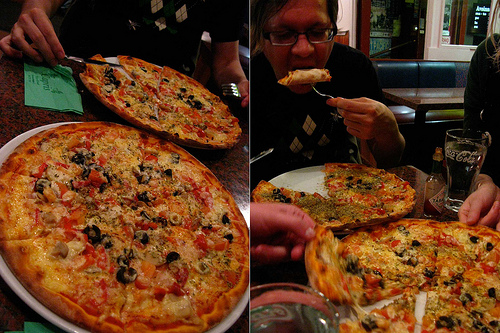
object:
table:
[381, 89, 463, 162]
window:
[367, 0, 500, 62]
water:
[248, 300, 332, 332]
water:
[444, 141, 488, 199]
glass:
[444, 128, 491, 214]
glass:
[251, 283, 341, 332]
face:
[260, 1, 337, 94]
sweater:
[250, 42, 384, 164]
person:
[250, 0, 436, 182]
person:
[457, 0, 500, 228]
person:
[2, 0, 250, 109]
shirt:
[252, 41, 388, 167]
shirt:
[461, 34, 500, 191]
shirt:
[51, 2, 244, 74]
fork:
[218, 79, 253, 120]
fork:
[309, 85, 335, 98]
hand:
[326, 96, 396, 141]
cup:
[444, 129, 492, 217]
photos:
[0, 0, 499, 333]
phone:
[221, 83, 242, 103]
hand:
[213, 59, 250, 107]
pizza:
[0, 54, 500, 331]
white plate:
[0, 121, 249, 332]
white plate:
[102, 47, 131, 69]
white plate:
[266, 165, 330, 198]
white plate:
[348, 287, 428, 333]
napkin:
[22, 60, 84, 118]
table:
[0, 36, 253, 333]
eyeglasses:
[262, 27, 339, 46]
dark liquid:
[445, 142, 482, 205]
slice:
[277, 67, 331, 86]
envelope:
[24, 62, 85, 115]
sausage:
[52, 241, 68, 255]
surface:
[0, 34, 252, 332]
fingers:
[252, 202, 326, 265]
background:
[261, 0, 500, 61]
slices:
[0, 121, 249, 332]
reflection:
[234, 186, 252, 233]